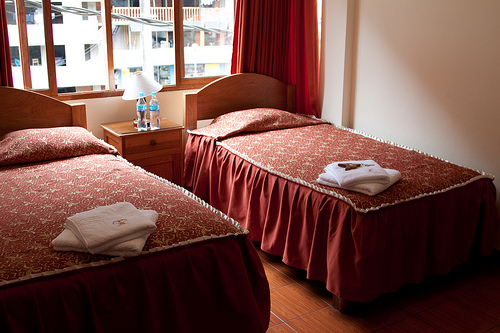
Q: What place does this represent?
A: It represents the hotel room.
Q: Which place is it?
A: It is a hotel room.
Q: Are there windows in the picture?
A: Yes, there is a window.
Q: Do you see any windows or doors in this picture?
A: Yes, there is a window.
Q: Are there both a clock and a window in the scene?
A: No, there is a window but no clocks.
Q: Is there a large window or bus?
A: Yes, there is a large window.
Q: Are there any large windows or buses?
A: Yes, there is a large window.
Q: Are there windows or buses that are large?
A: Yes, the window is large.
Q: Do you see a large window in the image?
A: Yes, there is a large window.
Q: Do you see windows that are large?
A: Yes, there is a window that is large.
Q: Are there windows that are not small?
A: Yes, there is a large window.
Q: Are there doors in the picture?
A: No, there are no doors.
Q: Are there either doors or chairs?
A: No, there are no doors or chairs.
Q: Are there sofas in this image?
A: No, there are no sofas.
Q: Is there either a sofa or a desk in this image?
A: No, there are no sofas or desks.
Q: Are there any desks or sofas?
A: No, there are no sofas or desks.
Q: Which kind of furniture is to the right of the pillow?
A: The piece of furniture is a drawer.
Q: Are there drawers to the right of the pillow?
A: Yes, there is a drawer to the right of the pillow.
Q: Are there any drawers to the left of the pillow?
A: No, the drawer is to the right of the pillow.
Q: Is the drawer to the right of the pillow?
A: Yes, the drawer is to the right of the pillow.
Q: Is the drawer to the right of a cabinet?
A: No, the drawer is to the right of the pillow.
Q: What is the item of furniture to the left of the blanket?
A: The piece of furniture is a drawer.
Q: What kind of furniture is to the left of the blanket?
A: The piece of furniture is a drawer.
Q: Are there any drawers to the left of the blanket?
A: Yes, there is a drawer to the left of the blanket.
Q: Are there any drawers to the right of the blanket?
A: No, the drawer is to the left of the blanket.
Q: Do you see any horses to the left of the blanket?
A: No, there is a drawer to the left of the blanket.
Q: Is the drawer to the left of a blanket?
A: Yes, the drawer is to the left of a blanket.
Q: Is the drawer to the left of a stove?
A: No, the drawer is to the left of a blanket.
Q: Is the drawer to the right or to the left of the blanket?
A: The drawer is to the left of the blanket.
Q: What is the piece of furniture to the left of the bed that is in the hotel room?
A: The piece of furniture is a drawer.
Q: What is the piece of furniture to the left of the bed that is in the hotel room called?
A: The piece of furniture is a drawer.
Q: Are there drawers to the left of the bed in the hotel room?
A: Yes, there is a drawer to the left of the bed.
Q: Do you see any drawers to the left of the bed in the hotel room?
A: Yes, there is a drawer to the left of the bed.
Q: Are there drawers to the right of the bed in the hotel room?
A: No, the drawer is to the left of the bed.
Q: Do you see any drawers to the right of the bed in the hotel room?
A: No, the drawer is to the left of the bed.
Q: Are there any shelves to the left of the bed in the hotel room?
A: No, there is a drawer to the left of the bed.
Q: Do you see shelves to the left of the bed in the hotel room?
A: No, there is a drawer to the left of the bed.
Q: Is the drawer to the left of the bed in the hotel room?
A: Yes, the drawer is to the left of the bed.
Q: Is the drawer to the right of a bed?
A: No, the drawer is to the left of a bed.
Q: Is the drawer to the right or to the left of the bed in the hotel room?
A: The drawer is to the left of the bed.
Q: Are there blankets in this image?
A: Yes, there is a blanket.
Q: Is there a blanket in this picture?
A: Yes, there is a blanket.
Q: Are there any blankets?
A: Yes, there is a blanket.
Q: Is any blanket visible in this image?
A: Yes, there is a blanket.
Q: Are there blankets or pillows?
A: Yes, there is a blanket.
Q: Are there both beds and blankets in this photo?
A: Yes, there are both a blanket and a bed.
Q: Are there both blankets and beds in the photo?
A: Yes, there are both a blanket and a bed.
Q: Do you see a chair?
A: No, there are no chairs.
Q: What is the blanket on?
A: The blanket is on the bed.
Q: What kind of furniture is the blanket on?
A: The blanket is on the bed.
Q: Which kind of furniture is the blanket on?
A: The blanket is on the bed.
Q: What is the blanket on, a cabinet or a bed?
A: The blanket is on a bed.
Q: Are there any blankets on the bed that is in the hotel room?
A: Yes, there is a blanket on the bed.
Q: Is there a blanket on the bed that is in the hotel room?
A: Yes, there is a blanket on the bed.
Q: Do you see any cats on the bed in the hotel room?
A: No, there is a blanket on the bed.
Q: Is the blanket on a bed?
A: Yes, the blanket is on a bed.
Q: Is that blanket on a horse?
A: No, the blanket is on a bed.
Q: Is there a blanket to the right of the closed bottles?
A: Yes, there is a blanket to the right of the bottles.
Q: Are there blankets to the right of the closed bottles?
A: Yes, there is a blanket to the right of the bottles.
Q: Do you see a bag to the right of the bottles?
A: No, there is a blanket to the right of the bottles.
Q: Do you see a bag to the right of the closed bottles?
A: No, there is a blanket to the right of the bottles.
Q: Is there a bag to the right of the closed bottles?
A: No, there is a blanket to the right of the bottles.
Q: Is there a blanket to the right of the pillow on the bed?
A: Yes, there is a blanket to the right of the pillow.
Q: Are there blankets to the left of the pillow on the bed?
A: No, the blanket is to the right of the pillow.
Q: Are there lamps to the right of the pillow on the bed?
A: No, there is a blanket to the right of the pillow.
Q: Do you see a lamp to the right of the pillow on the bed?
A: No, there is a blanket to the right of the pillow.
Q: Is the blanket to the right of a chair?
A: No, the blanket is to the right of the pillow.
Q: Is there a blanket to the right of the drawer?
A: Yes, there is a blanket to the right of the drawer.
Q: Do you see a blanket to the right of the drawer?
A: Yes, there is a blanket to the right of the drawer.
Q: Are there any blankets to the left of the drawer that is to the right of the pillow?
A: No, the blanket is to the right of the drawer.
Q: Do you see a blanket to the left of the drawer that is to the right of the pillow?
A: No, the blanket is to the right of the drawer.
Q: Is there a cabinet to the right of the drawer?
A: No, there is a blanket to the right of the drawer.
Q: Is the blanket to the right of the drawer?
A: Yes, the blanket is to the right of the drawer.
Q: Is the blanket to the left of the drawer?
A: No, the blanket is to the right of the drawer.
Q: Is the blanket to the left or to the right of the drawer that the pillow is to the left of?
A: The blanket is to the right of the drawer.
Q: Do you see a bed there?
A: Yes, there is a bed.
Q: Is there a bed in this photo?
A: Yes, there is a bed.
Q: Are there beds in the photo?
A: Yes, there is a bed.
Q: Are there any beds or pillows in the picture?
A: Yes, there is a bed.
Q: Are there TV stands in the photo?
A: No, there are no TV stands.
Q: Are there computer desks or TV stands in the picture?
A: No, there are no TV stands or computer desks.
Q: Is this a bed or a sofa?
A: This is a bed.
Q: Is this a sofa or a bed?
A: This is a bed.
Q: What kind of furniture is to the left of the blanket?
A: The piece of furniture is a bed.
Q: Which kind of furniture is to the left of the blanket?
A: The piece of furniture is a bed.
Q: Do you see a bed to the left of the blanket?
A: Yes, there is a bed to the left of the blanket.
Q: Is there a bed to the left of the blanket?
A: Yes, there is a bed to the left of the blanket.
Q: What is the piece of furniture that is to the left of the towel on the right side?
A: The piece of furniture is a bed.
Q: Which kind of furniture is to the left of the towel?
A: The piece of furniture is a bed.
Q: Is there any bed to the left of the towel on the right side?
A: Yes, there is a bed to the left of the towel.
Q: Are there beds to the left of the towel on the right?
A: Yes, there is a bed to the left of the towel.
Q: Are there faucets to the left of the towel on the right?
A: No, there is a bed to the left of the towel.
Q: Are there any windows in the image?
A: Yes, there are windows.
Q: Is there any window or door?
A: Yes, there are windows.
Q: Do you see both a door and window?
A: No, there are windows but no doors.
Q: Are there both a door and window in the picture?
A: No, there are windows but no doors.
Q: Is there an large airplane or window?
A: Yes, there are large windows.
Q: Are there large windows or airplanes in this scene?
A: Yes, there are large windows.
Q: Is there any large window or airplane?
A: Yes, there are large windows.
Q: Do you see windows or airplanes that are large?
A: Yes, the windows are large.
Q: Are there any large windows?
A: Yes, there are large windows.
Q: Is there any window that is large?
A: Yes, there are windows that are large.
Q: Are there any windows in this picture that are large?
A: Yes, there are windows that are large.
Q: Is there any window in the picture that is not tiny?
A: Yes, there are large windows.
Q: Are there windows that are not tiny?
A: Yes, there are large windows.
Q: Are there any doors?
A: No, there are no doors.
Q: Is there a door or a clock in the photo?
A: No, there are no doors or clocks.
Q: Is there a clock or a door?
A: No, there are no doors or clocks.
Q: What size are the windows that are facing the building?
A: The windows are large.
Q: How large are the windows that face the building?
A: The windows are large.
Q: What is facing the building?
A: The windows are facing the building.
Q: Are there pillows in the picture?
A: Yes, there is a pillow.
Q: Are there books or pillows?
A: Yes, there is a pillow.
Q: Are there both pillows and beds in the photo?
A: Yes, there are both a pillow and a bed.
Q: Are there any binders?
A: No, there are no binders.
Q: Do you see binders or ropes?
A: No, there are no binders or ropes.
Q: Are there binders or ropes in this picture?
A: No, there are no binders or ropes.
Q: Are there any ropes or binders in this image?
A: No, there are no binders or ropes.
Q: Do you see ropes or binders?
A: No, there are no binders or ropes.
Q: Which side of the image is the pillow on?
A: The pillow is on the left of the image.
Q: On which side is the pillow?
A: The pillow is on the left of the image.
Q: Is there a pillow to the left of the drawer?
A: Yes, there is a pillow to the left of the drawer.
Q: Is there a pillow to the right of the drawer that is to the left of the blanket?
A: No, the pillow is to the left of the drawer.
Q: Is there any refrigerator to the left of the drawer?
A: No, there is a pillow to the left of the drawer.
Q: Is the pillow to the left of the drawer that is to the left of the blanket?
A: Yes, the pillow is to the left of the drawer.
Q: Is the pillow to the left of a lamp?
A: No, the pillow is to the left of the drawer.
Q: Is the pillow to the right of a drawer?
A: No, the pillow is to the left of a drawer.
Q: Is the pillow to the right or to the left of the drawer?
A: The pillow is to the left of the drawer.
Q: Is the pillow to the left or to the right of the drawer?
A: The pillow is to the left of the drawer.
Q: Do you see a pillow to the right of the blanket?
A: No, the pillow is to the left of the blanket.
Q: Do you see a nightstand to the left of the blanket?
A: No, there is a pillow to the left of the blanket.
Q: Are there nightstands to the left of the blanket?
A: No, there is a pillow to the left of the blanket.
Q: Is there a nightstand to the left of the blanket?
A: No, there is a pillow to the left of the blanket.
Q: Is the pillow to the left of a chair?
A: No, the pillow is to the left of the blanket.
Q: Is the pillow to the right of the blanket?
A: No, the pillow is to the left of the blanket.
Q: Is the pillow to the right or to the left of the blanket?
A: The pillow is to the left of the blanket.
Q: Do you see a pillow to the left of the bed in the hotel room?
A: Yes, there is a pillow to the left of the bed.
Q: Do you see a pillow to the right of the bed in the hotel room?
A: No, the pillow is to the left of the bed.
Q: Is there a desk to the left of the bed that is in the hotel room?
A: No, there is a pillow to the left of the bed.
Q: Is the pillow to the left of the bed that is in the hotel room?
A: Yes, the pillow is to the left of the bed.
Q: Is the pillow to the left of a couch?
A: No, the pillow is to the left of the bed.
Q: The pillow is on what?
A: The pillow is on the bed.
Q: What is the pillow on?
A: The pillow is on the bed.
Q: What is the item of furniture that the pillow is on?
A: The piece of furniture is a bed.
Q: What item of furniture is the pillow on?
A: The pillow is on the bed.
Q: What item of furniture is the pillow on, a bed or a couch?
A: The pillow is on a bed.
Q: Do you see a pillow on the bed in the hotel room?
A: Yes, there is a pillow on the bed.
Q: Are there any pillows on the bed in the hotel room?
A: Yes, there is a pillow on the bed.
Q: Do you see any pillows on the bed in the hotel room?
A: Yes, there is a pillow on the bed.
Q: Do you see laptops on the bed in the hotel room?
A: No, there is a pillow on the bed.